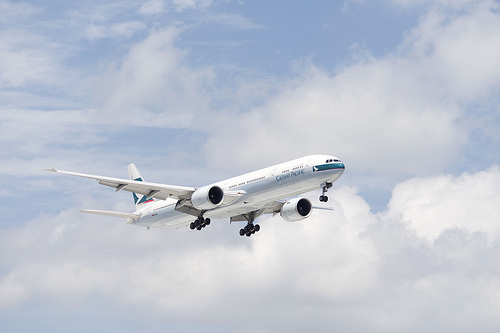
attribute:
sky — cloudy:
[2, 1, 497, 324]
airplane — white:
[47, 153, 359, 252]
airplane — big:
[49, 150, 350, 248]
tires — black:
[182, 206, 262, 236]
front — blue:
[312, 159, 349, 179]